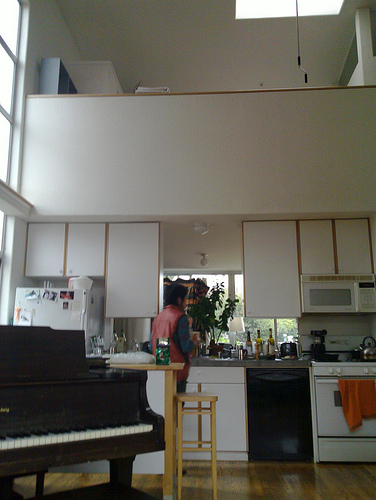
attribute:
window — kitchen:
[245, 309, 303, 363]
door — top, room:
[25, 279, 105, 355]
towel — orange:
[329, 381, 359, 420]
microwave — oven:
[242, 265, 370, 364]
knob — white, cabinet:
[335, 356, 356, 378]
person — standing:
[154, 280, 198, 412]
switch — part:
[112, 333, 145, 365]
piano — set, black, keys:
[2, 297, 162, 462]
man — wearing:
[115, 257, 217, 473]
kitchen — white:
[3, 212, 349, 481]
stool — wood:
[171, 373, 237, 471]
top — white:
[278, 260, 368, 323]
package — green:
[166, 327, 257, 408]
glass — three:
[89, 302, 141, 368]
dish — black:
[262, 384, 298, 450]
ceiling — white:
[158, 30, 224, 97]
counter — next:
[93, 338, 166, 393]